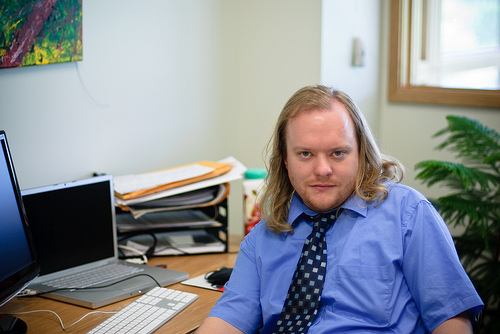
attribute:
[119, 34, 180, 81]
wall — white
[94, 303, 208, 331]
keyborad — white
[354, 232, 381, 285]
shirt — blue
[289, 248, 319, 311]
tie — blue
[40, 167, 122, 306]
laptop — open